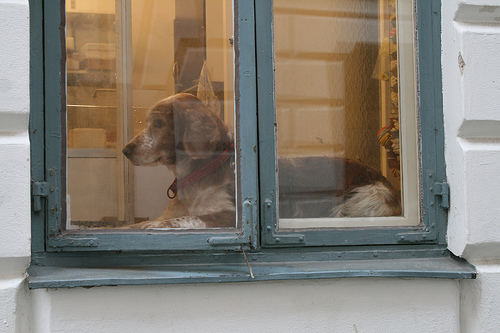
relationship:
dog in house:
[126, 98, 398, 231] [0, 2, 499, 332]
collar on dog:
[166, 144, 234, 201] [126, 98, 398, 231]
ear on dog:
[181, 106, 223, 162] [126, 98, 398, 231]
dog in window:
[126, 98, 398, 231] [65, 1, 235, 227]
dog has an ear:
[126, 98, 398, 231] [181, 106, 223, 162]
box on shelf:
[71, 127, 112, 149] [65, 0, 119, 158]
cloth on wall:
[197, 60, 231, 126] [276, 7, 378, 167]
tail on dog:
[326, 183, 396, 220] [126, 98, 398, 231]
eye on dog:
[153, 117, 166, 130] [126, 98, 398, 231]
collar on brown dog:
[166, 144, 234, 201] [126, 98, 398, 231]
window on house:
[65, 1, 235, 227] [0, 2, 499, 332]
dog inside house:
[126, 98, 398, 231] [0, 2, 499, 332]